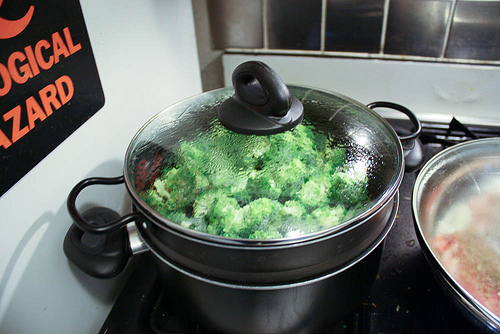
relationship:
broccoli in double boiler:
[137, 117, 375, 242] [62, 52, 428, 329]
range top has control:
[94, 104, 499, 331] [436, 117, 478, 152]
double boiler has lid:
[62, 52, 428, 333] [132, 59, 399, 224]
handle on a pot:
[366, 94, 425, 148] [81, 59, 410, 330]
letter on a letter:
[0, 0, 92, 137] [0, 0, 92, 137]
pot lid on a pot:
[104, 77, 416, 243] [70, 156, 420, 331]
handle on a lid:
[45, 207, 137, 289] [106, 76, 411, 253]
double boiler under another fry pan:
[62, 52, 428, 333] [407, 127, 499, 332]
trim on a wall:
[217, 33, 497, 80] [214, 49, 494, 127]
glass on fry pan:
[449, 151, 491, 271] [407, 127, 496, 332]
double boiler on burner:
[62, 52, 428, 329] [134, 274, 379, 331]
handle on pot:
[226, 42, 306, 139] [53, 46, 432, 323]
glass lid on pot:
[153, 85, 389, 245] [95, 82, 435, 311]